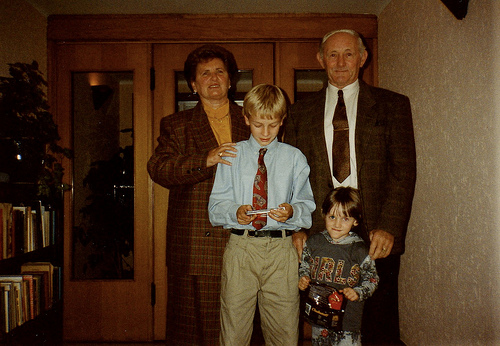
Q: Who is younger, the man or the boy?
A: The boy is younger than the man.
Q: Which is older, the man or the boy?
A: The man is older than the boy.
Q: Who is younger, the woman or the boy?
A: The boy is younger than the woman.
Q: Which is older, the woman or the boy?
A: The woman is older than the boy.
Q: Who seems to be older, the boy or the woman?
A: The woman is older than the boy.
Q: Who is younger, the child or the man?
A: The child is younger than the man.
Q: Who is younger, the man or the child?
A: The child is younger than the man.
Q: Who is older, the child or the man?
A: The man is older than the child.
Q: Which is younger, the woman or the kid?
A: The kid is younger than the woman.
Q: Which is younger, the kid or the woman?
A: The kid is younger than the woman.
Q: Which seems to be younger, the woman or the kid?
A: The kid is younger than the woman.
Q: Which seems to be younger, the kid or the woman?
A: The kid is younger than the woman.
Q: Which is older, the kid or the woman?
A: The woman is older than the kid.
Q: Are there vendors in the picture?
A: No, there are no vendors.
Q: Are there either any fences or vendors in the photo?
A: No, there are no vendors or fences.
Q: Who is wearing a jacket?
A: The man is wearing a jacket.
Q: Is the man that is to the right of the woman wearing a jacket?
A: Yes, the man is wearing a jacket.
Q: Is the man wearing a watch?
A: No, the man is wearing a jacket.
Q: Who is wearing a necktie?
A: The man is wearing a necktie.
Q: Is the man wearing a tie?
A: Yes, the man is wearing a tie.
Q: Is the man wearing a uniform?
A: No, the man is wearing a tie.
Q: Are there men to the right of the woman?
A: Yes, there is a man to the right of the woman.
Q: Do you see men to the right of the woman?
A: Yes, there is a man to the right of the woman.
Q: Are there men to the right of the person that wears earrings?
A: Yes, there is a man to the right of the woman.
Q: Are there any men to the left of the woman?
A: No, the man is to the right of the woman.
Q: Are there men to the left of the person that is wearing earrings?
A: No, the man is to the right of the woman.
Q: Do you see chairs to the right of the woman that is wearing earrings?
A: No, there is a man to the right of the woman.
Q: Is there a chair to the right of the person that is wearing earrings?
A: No, there is a man to the right of the woman.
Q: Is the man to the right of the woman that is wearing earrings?
A: Yes, the man is to the right of the woman.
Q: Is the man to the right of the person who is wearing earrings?
A: Yes, the man is to the right of the woman.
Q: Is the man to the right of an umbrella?
A: No, the man is to the right of the woman.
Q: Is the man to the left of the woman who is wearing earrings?
A: No, the man is to the right of the woman.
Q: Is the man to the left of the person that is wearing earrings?
A: No, the man is to the right of the woman.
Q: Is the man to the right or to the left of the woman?
A: The man is to the right of the woman.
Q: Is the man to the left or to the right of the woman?
A: The man is to the right of the woman.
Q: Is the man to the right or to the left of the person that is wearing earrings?
A: The man is to the right of the woman.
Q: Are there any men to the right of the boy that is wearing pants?
A: Yes, there is a man to the right of the boy.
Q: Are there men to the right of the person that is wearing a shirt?
A: Yes, there is a man to the right of the boy.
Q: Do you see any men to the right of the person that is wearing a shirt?
A: Yes, there is a man to the right of the boy.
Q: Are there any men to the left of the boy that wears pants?
A: No, the man is to the right of the boy.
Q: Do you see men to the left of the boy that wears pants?
A: No, the man is to the right of the boy.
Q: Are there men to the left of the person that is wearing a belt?
A: No, the man is to the right of the boy.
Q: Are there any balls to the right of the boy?
A: No, there is a man to the right of the boy.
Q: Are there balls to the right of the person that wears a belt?
A: No, there is a man to the right of the boy.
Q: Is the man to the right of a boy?
A: Yes, the man is to the right of a boy.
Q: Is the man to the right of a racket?
A: No, the man is to the right of a boy.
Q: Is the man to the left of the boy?
A: No, the man is to the right of the boy.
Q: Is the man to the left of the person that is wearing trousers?
A: No, the man is to the right of the boy.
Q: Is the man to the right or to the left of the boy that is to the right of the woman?
A: The man is to the right of the boy.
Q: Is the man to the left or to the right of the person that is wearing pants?
A: The man is to the right of the boy.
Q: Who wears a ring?
A: The man wears a ring.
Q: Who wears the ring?
A: The man wears a ring.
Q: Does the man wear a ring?
A: Yes, the man wears a ring.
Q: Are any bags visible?
A: No, there are no bags.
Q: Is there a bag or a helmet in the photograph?
A: No, there are no bags or helmets.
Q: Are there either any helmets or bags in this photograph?
A: No, there are no bags or helmets.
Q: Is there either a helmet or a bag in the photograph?
A: No, there are no bags or helmets.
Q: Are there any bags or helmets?
A: No, there are no bags or helmets.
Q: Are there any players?
A: No, there are no players.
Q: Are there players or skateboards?
A: No, there are no players or skateboards.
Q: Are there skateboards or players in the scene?
A: No, there are no players or skateboards.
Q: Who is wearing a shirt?
A: The boy is wearing a shirt.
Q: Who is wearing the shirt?
A: The boy is wearing a shirt.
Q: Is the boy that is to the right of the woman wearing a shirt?
A: Yes, the boy is wearing a shirt.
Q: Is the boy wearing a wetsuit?
A: No, the boy is wearing a shirt.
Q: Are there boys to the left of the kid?
A: Yes, there is a boy to the left of the kid.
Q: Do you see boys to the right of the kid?
A: No, the boy is to the left of the kid.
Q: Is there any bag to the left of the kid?
A: No, there is a boy to the left of the kid.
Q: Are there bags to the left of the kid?
A: No, there is a boy to the left of the kid.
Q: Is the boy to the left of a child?
A: Yes, the boy is to the left of a child.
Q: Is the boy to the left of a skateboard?
A: No, the boy is to the left of a child.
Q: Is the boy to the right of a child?
A: No, the boy is to the left of a child.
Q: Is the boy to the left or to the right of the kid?
A: The boy is to the left of the kid.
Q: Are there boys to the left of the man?
A: Yes, there is a boy to the left of the man.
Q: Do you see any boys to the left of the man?
A: Yes, there is a boy to the left of the man.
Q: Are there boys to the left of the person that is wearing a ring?
A: Yes, there is a boy to the left of the man.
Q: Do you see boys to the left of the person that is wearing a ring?
A: Yes, there is a boy to the left of the man.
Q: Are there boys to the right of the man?
A: No, the boy is to the left of the man.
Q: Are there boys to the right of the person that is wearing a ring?
A: No, the boy is to the left of the man.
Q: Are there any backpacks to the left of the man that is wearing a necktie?
A: No, there is a boy to the left of the man.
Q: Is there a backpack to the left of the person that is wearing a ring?
A: No, there is a boy to the left of the man.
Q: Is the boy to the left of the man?
A: Yes, the boy is to the left of the man.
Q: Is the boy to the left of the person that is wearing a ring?
A: Yes, the boy is to the left of the man.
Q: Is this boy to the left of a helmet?
A: No, the boy is to the left of the man.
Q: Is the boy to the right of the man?
A: No, the boy is to the left of the man.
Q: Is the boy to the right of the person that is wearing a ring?
A: No, the boy is to the left of the man.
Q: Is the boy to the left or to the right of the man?
A: The boy is to the left of the man.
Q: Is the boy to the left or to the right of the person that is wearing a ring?
A: The boy is to the left of the man.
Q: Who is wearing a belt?
A: The boy is wearing a belt.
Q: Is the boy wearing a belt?
A: Yes, the boy is wearing a belt.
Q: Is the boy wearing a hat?
A: No, the boy is wearing a belt.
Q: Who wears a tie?
A: The boy wears a tie.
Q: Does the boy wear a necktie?
A: Yes, the boy wears a necktie.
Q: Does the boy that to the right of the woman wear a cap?
A: No, the boy wears a necktie.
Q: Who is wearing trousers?
A: The boy is wearing trousers.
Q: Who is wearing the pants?
A: The boy is wearing trousers.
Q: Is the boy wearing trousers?
A: Yes, the boy is wearing trousers.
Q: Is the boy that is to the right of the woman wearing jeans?
A: No, the boy is wearing trousers.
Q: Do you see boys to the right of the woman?
A: Yes, there is a boy to the right of the woman.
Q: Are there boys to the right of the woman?
A: Yes, there is a boy to the right of the woman.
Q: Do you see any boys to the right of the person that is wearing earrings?
A: Yes, there is a boy to the right of the woman.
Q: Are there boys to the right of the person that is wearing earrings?
A: Yes, there is a boy to the right of the woman.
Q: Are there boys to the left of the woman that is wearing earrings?
A: No, the boy is to the right of the woman.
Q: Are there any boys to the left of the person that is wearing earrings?
A: No, the boy is to the right of the woman.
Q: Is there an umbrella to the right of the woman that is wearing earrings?
A: No, there is a boy to the right of the woman.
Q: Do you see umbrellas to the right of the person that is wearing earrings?
A: No, there is a boy to the right of the woman.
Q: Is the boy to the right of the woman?
A: Yes, the boy is to the right of the woman.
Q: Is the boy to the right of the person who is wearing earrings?
A: Yes, the boy is to the right of the woman.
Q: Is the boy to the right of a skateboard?
A: No, the boy is to the right of the woman.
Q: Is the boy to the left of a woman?
A: No, the boy is to the right of a woman.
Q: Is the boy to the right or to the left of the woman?
A: The boy is to the right of the woman.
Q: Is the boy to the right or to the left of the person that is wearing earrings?
A: The boy is to the right of the woman.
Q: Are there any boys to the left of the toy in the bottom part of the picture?
A: Yes, there is a boy to the left of the toy.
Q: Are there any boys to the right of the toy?
A: No, the boy is to the left of the toy.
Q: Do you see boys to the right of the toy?
A: No, the boy is to the left of the toy.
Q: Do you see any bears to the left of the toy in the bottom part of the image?
A: No, there is a boy to the left of the toy.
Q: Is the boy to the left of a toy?
A: Yes, the boy is to the left of a toy.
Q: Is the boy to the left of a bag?
A: No, the boy is to the left of a toy.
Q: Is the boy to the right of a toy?
A: No, the boy is to the left of a toy.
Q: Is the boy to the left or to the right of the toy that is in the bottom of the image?
A: The boy is to the left of the toy.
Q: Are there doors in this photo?
A: Yes, there is a door.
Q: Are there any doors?
A: Yes, there is a door.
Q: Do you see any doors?
A: Yes, there is a door.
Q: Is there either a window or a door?
A: Yes, there is a door.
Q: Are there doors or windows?
A: Yes, there is a door.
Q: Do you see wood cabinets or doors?
A: Yes, there is a wood door.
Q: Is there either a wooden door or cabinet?
A: Yes, there is a wood door.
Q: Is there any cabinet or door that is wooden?
A: Yes, the door is wooden.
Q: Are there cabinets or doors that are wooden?
A: Yes, the door is wooden.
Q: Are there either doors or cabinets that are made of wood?
A: Yes, the door is made of wood.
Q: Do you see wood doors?
A: Yes, there is a wood door.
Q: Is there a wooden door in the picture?
A: Yes, there is a wood door.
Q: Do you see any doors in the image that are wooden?
A: Yes, there is a door that is wooden.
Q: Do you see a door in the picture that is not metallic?
A: Yes, there is a wooden door.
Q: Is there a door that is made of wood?
A: Yes, there is a door that is made of wood.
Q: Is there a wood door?
A: Yes, there is a door that is made of wood.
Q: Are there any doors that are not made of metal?
A: Yes, there is a door that is made of wood.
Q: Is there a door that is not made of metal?
A: Yes, there is a door that is made of wood.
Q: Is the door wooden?
A: Yes, the door is wooden.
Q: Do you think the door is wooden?
A: Yes, the door is wooden.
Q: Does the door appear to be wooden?
A: Yes, the door is wooden.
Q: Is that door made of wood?
A: Yes, the door is made of wood.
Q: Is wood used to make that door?
A: Yes, the door is made of wood.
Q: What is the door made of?
A: The door is made of wood.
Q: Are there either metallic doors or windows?
A: No, there is a door but it is wooden.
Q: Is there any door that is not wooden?
A: No, there is a door but it is wooden.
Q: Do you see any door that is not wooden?
A: No, there is a door but it is wooden.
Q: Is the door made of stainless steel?
A: No, the door is made of wood.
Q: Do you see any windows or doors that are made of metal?
A: No, there is a door but it is made of wood.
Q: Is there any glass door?
A: No, there is a door but it is made of wood.